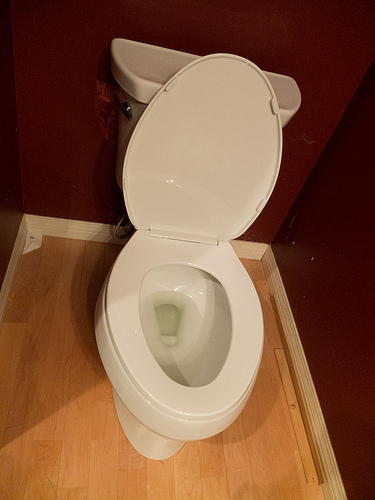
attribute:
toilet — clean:
[91, 36, 300, 461]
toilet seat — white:
[103, 229, 266, 419]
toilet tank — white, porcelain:
[106, 35, 301, 192]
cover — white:
[120, 51, 283, 245]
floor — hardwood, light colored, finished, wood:
[1, 233, 327, 499]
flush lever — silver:
[111, 88, 133, 123]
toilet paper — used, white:
[19, 224, 46, 260]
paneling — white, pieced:
[2, 211, 349, 499]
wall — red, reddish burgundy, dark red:
[1, 0, 374, 499]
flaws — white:
[93, 77, 121, 148]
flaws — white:
[287, 128, 318, 152]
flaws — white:
[285, 208, 316, 302]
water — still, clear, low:
[143, 286, 200, 361]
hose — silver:
[111, 207, 134, 241]